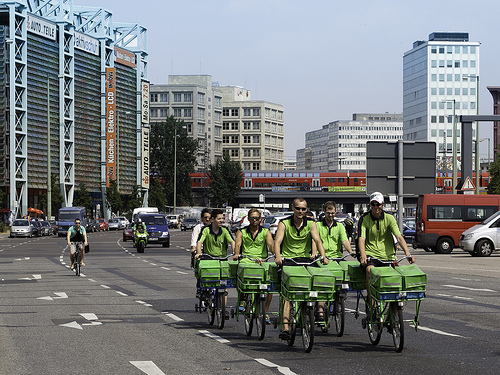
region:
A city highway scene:
[3, 3, 494, 372]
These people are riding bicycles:
[191, 190, 430, 356]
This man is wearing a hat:
[366, 191, 387, 216]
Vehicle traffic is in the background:
[9, 202, 181, 249]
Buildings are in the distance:
[150, 28, 483, 173]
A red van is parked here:
[411, 191, 498, 254]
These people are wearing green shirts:
[196, 191, 421, 266]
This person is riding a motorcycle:
[131, 215, 152, 255]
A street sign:
[460, 175, 477, 193]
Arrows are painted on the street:
[11, 254, 102, 334]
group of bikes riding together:
[162, 192, 487, 373]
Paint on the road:
[91, 267, 219, 368]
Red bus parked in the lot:
[407, 178, 497, 247]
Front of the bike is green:
[282, 259, 349, 313]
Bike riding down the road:
[57, 216, 100, 278]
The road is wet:
[305, 335, 341, 367]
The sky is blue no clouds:
[242, 25, 376, 122]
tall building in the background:
[404, 39, 499, 173]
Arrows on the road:
[35, 273, 92, 340]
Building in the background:
[15, 20, 150, 170]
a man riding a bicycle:
[196, 210, 231, 327]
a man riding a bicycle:
[235, 210, 273, 337]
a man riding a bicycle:
[270, 197, 337, 348]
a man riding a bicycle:
[314, 198, 361, 336]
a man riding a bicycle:
[353, 190, 428, 351]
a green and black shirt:
[195, 220, 232, 257]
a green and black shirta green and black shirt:
[279, 215, 311, 255]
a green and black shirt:
[315, 218, 347, 262]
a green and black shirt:
[354, 208, 400, 265]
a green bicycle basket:
[197, 259, 232, 279]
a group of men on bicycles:
[185, 178, 417, 353]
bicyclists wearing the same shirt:
[176, 189, 426, 355]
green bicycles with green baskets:
[188, 173, 473, 349]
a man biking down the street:
[63, 212, 105, 295]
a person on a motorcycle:
[132, 211, 154, 256]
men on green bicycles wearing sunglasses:
[242, 193, 322, 342]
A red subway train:
[146, 160, 498, 210]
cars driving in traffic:
[14, 187, 198, 247]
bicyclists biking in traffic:
[61, 178, 457, 353]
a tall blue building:
[1, 2, 166, 208]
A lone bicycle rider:
[64, 218, 91, 278]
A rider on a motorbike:
[133, 217, 149, 259]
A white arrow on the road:
[57, 306, 106, 331]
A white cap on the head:
[370, 188, 385, 205]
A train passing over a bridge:
[256, 172, 358, 187]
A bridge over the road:
[248, 191, 358, 199]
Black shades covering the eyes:
[294, 206, 308, 212]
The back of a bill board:
[368, 138, 438, 195]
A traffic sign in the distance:
[460, 173, 475, 190]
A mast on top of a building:
[197, 53, 202, 73]